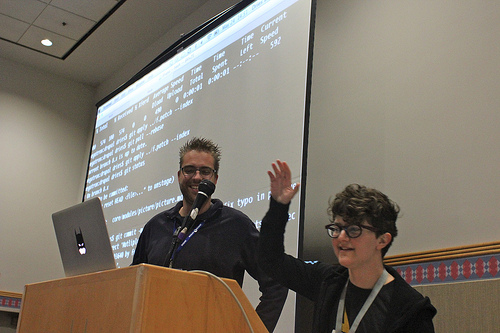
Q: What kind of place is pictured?
A: It is a display.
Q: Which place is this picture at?
A: It is at the display.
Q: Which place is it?
A: It is a display.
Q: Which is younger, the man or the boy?
A: The boy is younger than the man.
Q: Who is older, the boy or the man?
A: The man is older than the boy.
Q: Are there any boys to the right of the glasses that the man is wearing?
A: Yes, there is a boy to the right of the glasses.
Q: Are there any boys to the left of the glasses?
A: No, the boy is to the right of the glasses.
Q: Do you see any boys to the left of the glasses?
A: No, the boy is to the right of the glasses.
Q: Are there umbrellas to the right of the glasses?
A: No, there is a boy to the right of the glasses.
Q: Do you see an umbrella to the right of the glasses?
A: No, there is a boy to the right of the glasses.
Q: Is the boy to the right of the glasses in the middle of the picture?
A: Yes, the boy is to the right of the glasses.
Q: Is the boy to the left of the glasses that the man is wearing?
A: No, the boy is to the right of the glasses.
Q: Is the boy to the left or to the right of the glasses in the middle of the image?
A: The boy is to the right of the glasses.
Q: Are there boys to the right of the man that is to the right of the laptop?
A: Yes, there is a boy to the right of the man.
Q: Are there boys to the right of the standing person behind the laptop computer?
A: Yes, there is a boy to the right of the man.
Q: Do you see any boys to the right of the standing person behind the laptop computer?
A: Yes, there is a boy to the right of the man.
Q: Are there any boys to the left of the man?
A: No, the boy is to the right of the man.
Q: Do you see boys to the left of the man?
A: No, the boy is to the right of the man.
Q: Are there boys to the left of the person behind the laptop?
A: No, the boy is to the right of the man.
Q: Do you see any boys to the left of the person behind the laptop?
A: No, the boy is to the right of the man.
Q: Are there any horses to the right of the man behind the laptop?
A: No, there is a boy to the right of the man.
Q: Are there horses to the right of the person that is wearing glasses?
A: No, there is a boy to the right of the man.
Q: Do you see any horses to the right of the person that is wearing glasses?
A: No, there is a boy to the right of the man.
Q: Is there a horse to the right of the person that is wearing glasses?
A: No, there is a boy to the right of the man.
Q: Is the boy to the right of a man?
A: Yes, the boy is to the right of a man.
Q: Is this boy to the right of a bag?
A: No, the boy is to the right of a man.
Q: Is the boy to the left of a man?
A: No, the boy is to the right of a man.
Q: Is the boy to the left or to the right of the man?
A: The boy is to the right of the man.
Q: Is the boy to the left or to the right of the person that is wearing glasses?
A: The boy is to the right of the man.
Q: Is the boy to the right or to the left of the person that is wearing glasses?
A: The boy is to the right of the man.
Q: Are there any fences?
A: No, there are no fences.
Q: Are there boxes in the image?
A: No, there are no boxes.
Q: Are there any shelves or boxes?
A: No, there are no boxes or shelves.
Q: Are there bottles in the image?
A: No, there are no bottles.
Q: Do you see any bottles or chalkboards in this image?
A: No, there are no bottles or chalkboards.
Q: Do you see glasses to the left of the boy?
A: Yes, there are glasses to the left of the boy.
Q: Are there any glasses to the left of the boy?
A: Yes, there are glasses to the left of the boy.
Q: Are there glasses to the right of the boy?
A: No, the glasses are to the left of the boy.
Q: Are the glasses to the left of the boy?
A: Yes, the glasses are to the left of the boy.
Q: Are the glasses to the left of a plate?
A: No, the glasses are to the left of the boy.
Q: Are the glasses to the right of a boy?
A: No, the glasses are to the left of a boy.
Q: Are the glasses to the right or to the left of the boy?
A: The glasses are to the left of the boy.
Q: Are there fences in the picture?
A: No, there are no fences.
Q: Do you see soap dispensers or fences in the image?
A: No, there are no fences or soap dispensers.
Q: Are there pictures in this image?
A: No, there are no pictures.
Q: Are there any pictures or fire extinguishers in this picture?
A: No, there are no pictures or fire extinguishers.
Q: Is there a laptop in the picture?
A: Yes, there is a laptop.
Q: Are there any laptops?
A: Yes, there is a laptop.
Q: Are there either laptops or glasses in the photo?
A: Yes, there is a laptop.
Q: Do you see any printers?
A: No, there are no printers.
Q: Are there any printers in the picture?
A: No, there are no printers.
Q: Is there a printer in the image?
A: No, there are no printers.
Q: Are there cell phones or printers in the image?
A: No, there are no printers or cell phones.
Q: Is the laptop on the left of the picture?
A: Yes, the laptop is on the left of the image.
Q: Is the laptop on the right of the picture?
A: No, the laptop is on the left of the image.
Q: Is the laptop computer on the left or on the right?
A: The laptop computer is on the left of the image.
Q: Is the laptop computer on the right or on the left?
A: The laptop computer is on the left of the image.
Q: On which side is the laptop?
A: The laptop is on the left of the image.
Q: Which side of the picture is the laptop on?
A: The laptop is on the left of the image.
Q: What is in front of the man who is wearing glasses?
A: The laptop is in front of the man.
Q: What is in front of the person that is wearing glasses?
A: The laptop is in front of the man.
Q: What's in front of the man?
A: The laptop is in front of the man.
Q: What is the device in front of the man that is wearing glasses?
A: The device is a laptop.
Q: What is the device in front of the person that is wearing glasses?
A: The device is a laptop.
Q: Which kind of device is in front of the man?
A: The device is a laptop.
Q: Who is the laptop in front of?
A: The laptop is in front of the man.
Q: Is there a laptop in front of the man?
A: Yes, there is a laptop in front of the man.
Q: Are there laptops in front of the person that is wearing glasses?
A: Yes, there is a laptop in front of the man.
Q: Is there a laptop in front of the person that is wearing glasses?
A: Yes, there is a laptop in front of the man.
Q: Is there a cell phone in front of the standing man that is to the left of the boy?
A: No, there is a laptop in front of the man.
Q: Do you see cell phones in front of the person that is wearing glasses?
A: No, there is a laptop in front of the man.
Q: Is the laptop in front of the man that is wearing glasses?
A: Yes, the laptop is in front of the man.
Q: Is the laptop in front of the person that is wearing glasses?
A: Yes, the laptop is in front of the man.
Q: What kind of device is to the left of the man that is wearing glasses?
A: The device is a laptop.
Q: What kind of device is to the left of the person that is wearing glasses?
A: The device is a laptop.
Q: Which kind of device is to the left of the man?
A: The device is a laptop.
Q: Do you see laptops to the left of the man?
A: Yes, there is a laptop to the left of the man.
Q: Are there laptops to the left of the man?
A: Yes, there is a laptop to the left of the man.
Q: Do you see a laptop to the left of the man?
A: Yes, there is a laptop to the left of the man.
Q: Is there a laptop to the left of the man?
A: Yes, there is a laptop to the left of the man.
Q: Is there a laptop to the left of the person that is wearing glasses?
A: Yes, there is a laptop to the left of the man.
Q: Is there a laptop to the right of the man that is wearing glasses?
A: No, the laptop is to the left of the man.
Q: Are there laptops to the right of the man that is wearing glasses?
A: No, the laptop is to the left of the man.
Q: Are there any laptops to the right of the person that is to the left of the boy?
A: No, the laptop is to the left of the man.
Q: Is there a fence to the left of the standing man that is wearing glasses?
A: No, there is a laptop to the left of the man.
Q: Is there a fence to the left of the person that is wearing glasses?
A: No, there is a laptop to the left of the man.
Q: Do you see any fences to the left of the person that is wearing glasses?
A: No, there is a laptop to the left of the man.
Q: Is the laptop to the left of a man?
A: Yes, the laptop is to the left of a man.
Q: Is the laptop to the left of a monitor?
A: No, the laptop is to the left of a man.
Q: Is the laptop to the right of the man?
A: No, the laptop is to the left of the man.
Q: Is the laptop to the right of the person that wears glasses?
A: No, the laptop is to the left of the man.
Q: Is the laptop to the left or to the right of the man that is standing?
A: The laptop is to the left of the man.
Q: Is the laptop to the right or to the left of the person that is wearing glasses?
A: The laptop is to the left of the man.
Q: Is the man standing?
A: Yes, the man is standing.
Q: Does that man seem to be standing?
A: Yes, the man is standing.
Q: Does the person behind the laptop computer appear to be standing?
A: Yes, the man is standing.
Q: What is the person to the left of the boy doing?
A: The man is standing.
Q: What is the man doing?
A: The man is standing.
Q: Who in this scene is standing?
A: The man is standing.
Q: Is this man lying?
A: No, the man is standing.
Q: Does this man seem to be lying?
A: No, the man is standing.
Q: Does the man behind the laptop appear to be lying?
A: No, the man is standing.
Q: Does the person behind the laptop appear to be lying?
A: No, the man is standing.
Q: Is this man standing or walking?
A: The man is standing.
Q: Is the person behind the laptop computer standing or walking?
A: The man is standing.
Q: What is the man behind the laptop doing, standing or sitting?
A: The man is standing.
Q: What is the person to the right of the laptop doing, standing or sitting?
A: The man is standing.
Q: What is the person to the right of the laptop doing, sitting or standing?
A: The man is standing.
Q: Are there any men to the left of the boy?
A: Yes, there is a man to the left of the boy.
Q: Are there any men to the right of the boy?
A: No, the man is to the left of the boy.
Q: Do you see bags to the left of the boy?
A: No, there is a man to the left of the boy.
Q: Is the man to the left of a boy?
A: Yes, the man is to the left of a boy.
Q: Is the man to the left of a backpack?
A: No, the man is to the left of a boy.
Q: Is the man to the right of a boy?
A: No, the man is to the left of a boy.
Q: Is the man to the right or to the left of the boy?
A: The man is to the left of the boy.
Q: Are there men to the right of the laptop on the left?
A: Yes, there is a man to the right of the laptop.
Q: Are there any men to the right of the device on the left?
A: Yes, there is a man to the right of the laptop.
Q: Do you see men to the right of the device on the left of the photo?
A: Yes, there is a man to the right of the laptop.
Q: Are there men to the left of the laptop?
A: No, the man is to the right of the laptop.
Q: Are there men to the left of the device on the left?
A: No, the man is to the right of the laptop.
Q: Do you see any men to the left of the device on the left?
A: No, the man is to the right of the laptop.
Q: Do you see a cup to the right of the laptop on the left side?
A: No, there is a man to the right of the laptop.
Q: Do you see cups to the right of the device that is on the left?
A: No, there is a man to the right of the laptop.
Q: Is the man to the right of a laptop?
A: Yes, the man is to the right of a laptop.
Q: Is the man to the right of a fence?
A: No, the man is to the right of a laptop.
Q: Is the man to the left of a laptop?
A: No, the man is to the right of a laptop.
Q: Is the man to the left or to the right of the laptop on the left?
A: The man is to the right of the laptop computer.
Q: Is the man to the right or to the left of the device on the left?
A: The man is to the right of the laptop computer.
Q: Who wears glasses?
A: The man wears glasses.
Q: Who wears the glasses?
A: The man wears glasses.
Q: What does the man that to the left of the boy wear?
A: The man wears glasses.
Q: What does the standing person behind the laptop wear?
A: The man wears glasses.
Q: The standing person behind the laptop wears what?
A: The man wears glasses.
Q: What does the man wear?
A: The man wears glasses.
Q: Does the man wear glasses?
A: Yes, the man wears glasses.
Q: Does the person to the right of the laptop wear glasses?
A: Yes, the man wears glasses.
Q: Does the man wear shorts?
A: No, the man wears glasses.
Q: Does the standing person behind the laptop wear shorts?
A: No, the man wears glasses.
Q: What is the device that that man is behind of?
A: The device is a laptop.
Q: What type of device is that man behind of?
A: The man is behind the laptop.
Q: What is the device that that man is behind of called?
A: The device is a laptop.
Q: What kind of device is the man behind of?
A: The man is behind the laptop.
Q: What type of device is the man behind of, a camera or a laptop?
A: The man is behind a laptop.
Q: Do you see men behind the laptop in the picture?
A: Yes, there is a man behind the laptop.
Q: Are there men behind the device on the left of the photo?
A: Yes, there is a man behind the laptop.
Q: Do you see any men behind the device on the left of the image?
A: Yes, there is a man behind the laptop.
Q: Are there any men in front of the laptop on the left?
A: No, the man is behind the laptop.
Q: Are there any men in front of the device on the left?
A: No, the man is behind the laptop.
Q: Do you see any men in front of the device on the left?
A: No, the man is behind the laptop.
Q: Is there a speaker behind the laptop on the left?
A: No, there is a man behind the laptop.